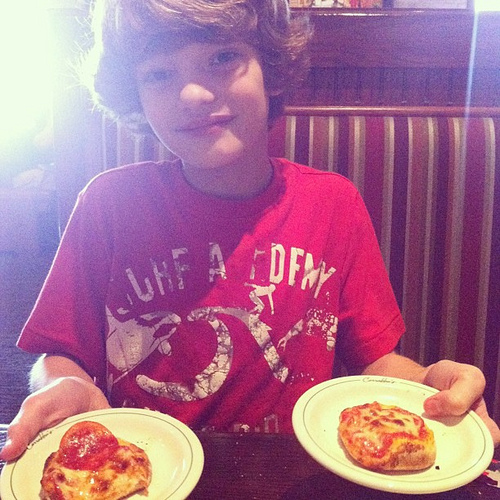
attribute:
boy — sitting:
[108, 30, 335, 244]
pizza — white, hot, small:
[345, 397, 440, 468]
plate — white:
[304, 390, 333, 438]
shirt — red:
[171, 202, 306, 319]